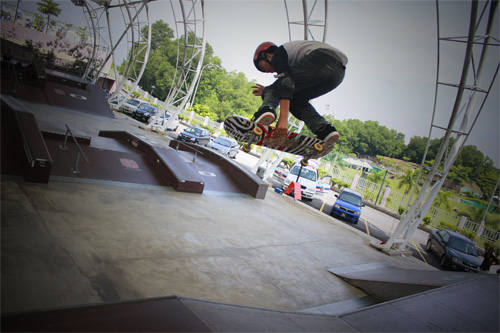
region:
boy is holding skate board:
[223, 37, 353, 180]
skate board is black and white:
[220, 110, 333, 180]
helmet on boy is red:
[247, 36, 278, 64]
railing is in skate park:
[50, 121, 105, 177]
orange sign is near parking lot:
[280, 175, 310, 211]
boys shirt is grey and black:
[265, 36, 366, 68]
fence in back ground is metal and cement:
[90, 77, 493, 242]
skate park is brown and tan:
[1, 45, 496, 325]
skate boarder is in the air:
[220, 40, 350, 166]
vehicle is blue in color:
[333, 184, 375, 231]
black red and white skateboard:
[223, 116, 332, 161]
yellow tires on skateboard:
[298, 143, 321, 168]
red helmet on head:
[251, 41, 275, 63]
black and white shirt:
[271, 40, 348, 75]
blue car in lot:
[333, 188, 365, 220]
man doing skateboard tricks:
[226, 43, 347, 157]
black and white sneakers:
[252, 108, 339, 145]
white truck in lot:
[284, 163, 316, 199]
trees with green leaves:
[132, 18, 221, 105]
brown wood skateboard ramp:
[6, 106, 266, 201]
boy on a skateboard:
[228, 27, 360, 178]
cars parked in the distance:
[110, 90, 235, 150]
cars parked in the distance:
[280, 160, 480, 265]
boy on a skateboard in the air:
[192, 16, 414, 184]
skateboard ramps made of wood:
[80, 147, 354, 316]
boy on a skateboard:
[92, 28, 423, 167]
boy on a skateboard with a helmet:
[179, 5, 466, 237]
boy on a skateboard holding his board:
[187, 14, 454, 214]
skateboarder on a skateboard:
[222, 39, 350, 166]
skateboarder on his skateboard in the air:
[221, 32, 373, 220]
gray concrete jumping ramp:
[329, 257, 491, 332]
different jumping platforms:
[1, 106, 268, 223]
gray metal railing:
[55, 120, 96, 178]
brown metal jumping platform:
[0, 35, 128, 117]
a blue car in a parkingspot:
[322, 185, 370, 236]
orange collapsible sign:
[281, 177, 307, 204]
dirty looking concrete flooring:
[0, 175, 378, 293]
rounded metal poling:
[371, 0, 498, 259]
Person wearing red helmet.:
[239, 38, 283, 69]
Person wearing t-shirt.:
[277, 33, 325, 64]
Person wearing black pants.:
[294, 63, 332, 105]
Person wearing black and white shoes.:
[252, 110, 349, 134]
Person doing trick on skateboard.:
[229, 90, 369, 177]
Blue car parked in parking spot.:
[320, 166, 377, 248]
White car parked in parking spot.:
[288, 158, 323, 208]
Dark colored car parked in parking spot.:
[428, 222, 478, 278]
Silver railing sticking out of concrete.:
[57, 119, 94, 188]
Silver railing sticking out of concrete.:
[165, 128, 213, 198]